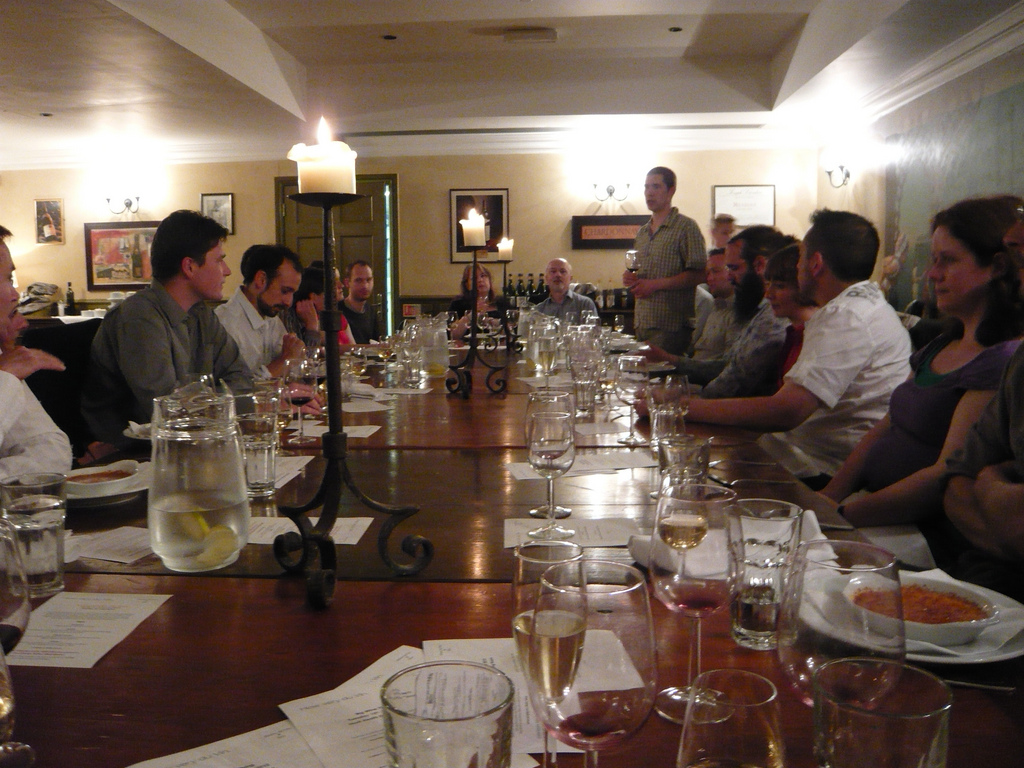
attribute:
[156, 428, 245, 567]
water — ice water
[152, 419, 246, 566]
water — ice water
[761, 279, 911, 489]
shirt — short-sleeved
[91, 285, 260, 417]
shirt — casual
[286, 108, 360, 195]
candle — closest, lit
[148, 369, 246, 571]
flask — larger, lemon water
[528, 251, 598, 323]
gentleman — older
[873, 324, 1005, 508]
top — purple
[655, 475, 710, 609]
glass — champaigne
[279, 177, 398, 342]
door — entrance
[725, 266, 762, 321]
beard — big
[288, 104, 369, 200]
candle — short, white, lit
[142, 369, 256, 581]
pitcher — clear, glass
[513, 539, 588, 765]
champagne flute — half full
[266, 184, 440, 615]
candle holder — tall, metal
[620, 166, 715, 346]
man — standing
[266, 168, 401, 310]
door — closed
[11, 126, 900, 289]
wall — light tan